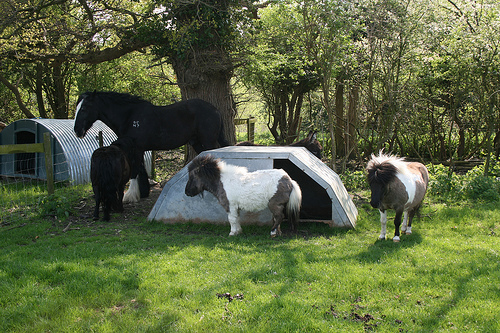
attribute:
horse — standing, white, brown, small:
[179, 153, 304, 243]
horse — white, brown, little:
[360, 144, 430, 247]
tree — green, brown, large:
[59, 8, 254, 178]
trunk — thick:
[171, 53, 242, 149]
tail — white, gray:
[285, 183, 305, 224]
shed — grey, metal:
[4, 115, 159, 195]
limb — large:
[35, 26, 185, 70]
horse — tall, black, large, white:
[69, 84, 230, 203]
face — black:
[65, 92, 103, 140]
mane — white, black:
[185, 155, 250, 180]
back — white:
[226, 172, 283, 206]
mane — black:
[90, 87, 145, 103]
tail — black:
[218, 117, 231, 147]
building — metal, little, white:
[151, 143, 362, 240]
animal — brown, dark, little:
[89, 139, 137, 225]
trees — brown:
[242, 10, 490, 158]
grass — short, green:
[36, 237, 495, 325]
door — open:
[270, 159, 336, 225]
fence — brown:
[237, 114, 260, 140]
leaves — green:
[290, 55, 318, 86]